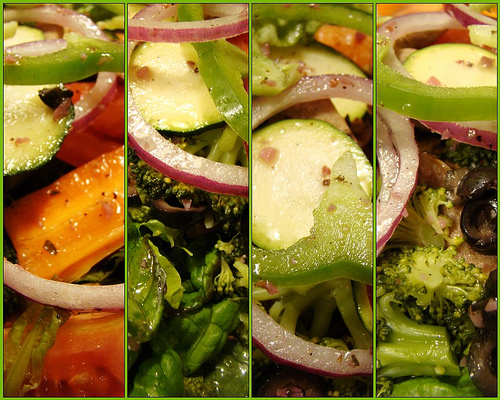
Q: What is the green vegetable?
A: Pepper.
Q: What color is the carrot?
A: Orange.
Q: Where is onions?
A: Mixed in.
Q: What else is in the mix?
A: Season.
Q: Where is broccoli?
A: In far right picture.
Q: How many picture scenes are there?
A: Four.